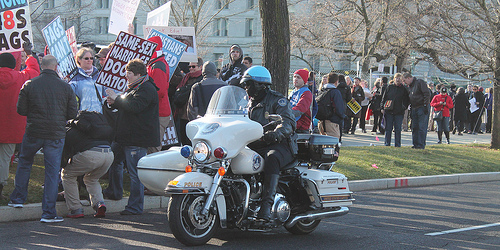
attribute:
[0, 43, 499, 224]
people — demonstrating, protesters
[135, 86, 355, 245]
motorcycle — white, police motorcycle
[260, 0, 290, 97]
tree — large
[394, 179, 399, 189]
line — red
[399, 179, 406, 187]
line — red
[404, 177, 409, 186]
line — red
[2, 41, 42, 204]
person — standing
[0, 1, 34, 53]
sign — picket sign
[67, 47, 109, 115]
person — blonde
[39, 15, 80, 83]
sign — picket sign, black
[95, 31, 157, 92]
sign — picket sign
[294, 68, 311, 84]
hat — red, knit, stocking cap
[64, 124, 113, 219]
man — bending, stooping, crouching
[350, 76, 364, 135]
man — standing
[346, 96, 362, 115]
sign — yellow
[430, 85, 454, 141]
woman — texting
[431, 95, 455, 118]
coat — red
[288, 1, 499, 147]
tree — leafless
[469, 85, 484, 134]
person — standing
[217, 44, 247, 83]
man — tall, light-skinned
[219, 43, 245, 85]
hoodie — gray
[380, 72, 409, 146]
person — standing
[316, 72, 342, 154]
person — standing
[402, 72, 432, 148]
person — standing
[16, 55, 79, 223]
person — standing, bald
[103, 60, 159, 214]
person — standing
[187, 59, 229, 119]
person — standing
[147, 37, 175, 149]
person — standing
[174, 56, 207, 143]
person — standing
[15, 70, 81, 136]
coat — black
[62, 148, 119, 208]
pants — khaki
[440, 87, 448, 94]
hat — black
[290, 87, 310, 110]
scarf — blue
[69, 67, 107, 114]
jacket — blue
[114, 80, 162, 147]
jacket — black